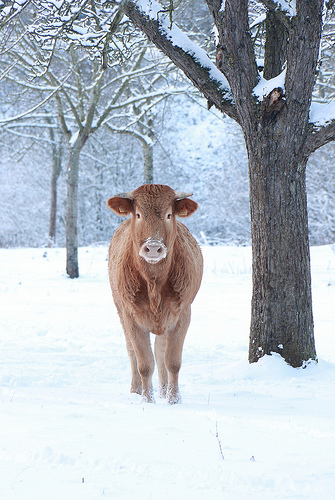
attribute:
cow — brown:
[94, 182, 217, 408]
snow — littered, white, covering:
[5, 247, 334, 447]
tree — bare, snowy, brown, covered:
[121, 0, 323, 371]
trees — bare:
[1, 0, 169, 292]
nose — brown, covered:
[141, 243, 167, 260]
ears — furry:
[101, 193, 199, 221]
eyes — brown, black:
[132, 206, 177, 227]